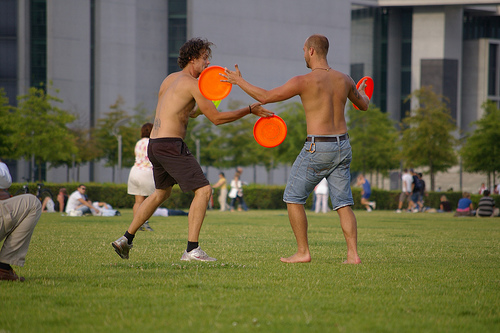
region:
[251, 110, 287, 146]
Round orange frisbee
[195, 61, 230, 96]
Round orange frisbee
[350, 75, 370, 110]
Round orange frisbee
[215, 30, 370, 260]
Man wearing blue denim shorts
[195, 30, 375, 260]
Man holding two orange frisbees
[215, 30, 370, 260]
Man wearing belt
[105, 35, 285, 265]
Man holding orange frisbee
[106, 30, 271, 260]
Man wearing black socks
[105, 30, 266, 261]
Man wearing black shorts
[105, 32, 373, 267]
Two shirtless men holding orange frisbees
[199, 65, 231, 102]
A orange frisbee in his hand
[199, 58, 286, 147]
Two frisbees in their hands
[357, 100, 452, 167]
Trees by the grassy field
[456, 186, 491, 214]
People sitting in the field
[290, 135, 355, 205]
The man is wearing shorts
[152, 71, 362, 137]
The men are not wearing shirts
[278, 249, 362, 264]
The man has no shoes on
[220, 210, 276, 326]
A grassy field benath the frisbee players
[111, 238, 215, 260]
This man has silver shoes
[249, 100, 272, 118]
The right hand of the man on the left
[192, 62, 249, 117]
Orange frisbee in man's hand.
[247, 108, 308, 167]
Orange frisbee in man's hand.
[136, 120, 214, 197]
Man wearing black shorts.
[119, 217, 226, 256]
Man wearing black socks.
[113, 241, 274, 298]
Man wearing tennis shoes.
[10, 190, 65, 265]
Person wearing khaki pants.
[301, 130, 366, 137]
Man wearing dark belt.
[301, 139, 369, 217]
Man wearing jean shorts.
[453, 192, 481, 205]
Person wearing blue shirt.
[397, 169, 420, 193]
Person wearing white shirt.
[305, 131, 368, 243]
man in jean shorts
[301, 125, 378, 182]
man wearing black belt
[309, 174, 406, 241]
jean shorts are blue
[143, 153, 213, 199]
man in maroon shorts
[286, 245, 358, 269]
man wearing no shoes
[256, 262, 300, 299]
grass is green and short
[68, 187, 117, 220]
man in white shirt sitting in grass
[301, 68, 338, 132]
man wearing no shirt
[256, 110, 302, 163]
man holding orange frisbee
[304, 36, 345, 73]
man has no hair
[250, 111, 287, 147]
circular orange plastic frisbee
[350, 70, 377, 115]
circular orange plastic frisbee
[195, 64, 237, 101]
circular orange plastic frisbee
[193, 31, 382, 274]
man touching two orange frisbees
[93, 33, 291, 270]
man in dark gray shorts throwing orange frisbee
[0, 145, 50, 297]
person in beige pants crouching in the middle of a green grassy field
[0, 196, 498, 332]
large green grassy field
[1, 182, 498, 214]
row of thick trimmed hedges around grassy field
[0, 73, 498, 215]
line of small trees around park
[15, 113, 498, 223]
many people walking and sitting within a park